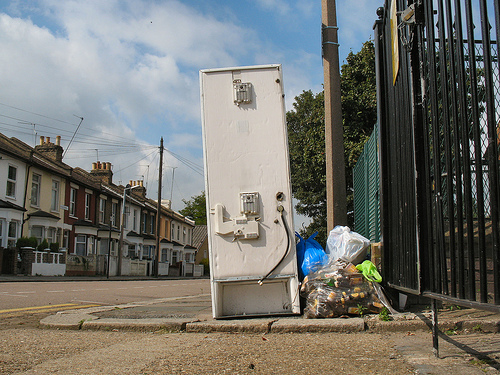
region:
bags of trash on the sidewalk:
[292, 216, 402, 333]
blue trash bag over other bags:
[296, 222, 334, 285]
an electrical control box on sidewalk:
[183, 52, 315, 331]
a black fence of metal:
[366, 0, 498, 345]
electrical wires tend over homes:
[1, 98, 203, 173]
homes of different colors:
[5, 128, 202, 285]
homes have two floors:
[1, 132, 206, 296]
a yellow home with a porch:
[16, 132, 71, 273]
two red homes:
[61, 159, 126, 275]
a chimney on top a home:
[26, 125, 69, 161]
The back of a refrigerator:
[195, 65, 307, 320]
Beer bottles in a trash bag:
[310, 268, 379, 318]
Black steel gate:
[420, 0, 499, 298]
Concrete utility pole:
[317, 2, 352, 314]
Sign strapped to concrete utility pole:
[313, 13, 346, 67]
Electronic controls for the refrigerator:
[215, 188, 270, 245]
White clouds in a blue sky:
[58, 13, 196, 107]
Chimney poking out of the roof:
[85, 155, 115, 187]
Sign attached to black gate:
[387, 1, 401, 82]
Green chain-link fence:
[347, 122, 377, 232]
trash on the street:
[292, 210, 440, 362]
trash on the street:
[282, 250, 403, 327]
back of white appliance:
[201, 54, 298, 320]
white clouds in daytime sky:
[67, 26, 176, 91]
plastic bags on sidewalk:
[294, 217, 376, 316]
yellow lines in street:
[10, 298, 87, 326]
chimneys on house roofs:
[36, 131, 151, 205]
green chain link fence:
[347, 128, 379, 232]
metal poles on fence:
[390, 45, 489, 266]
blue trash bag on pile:
[291, 227, 331, 279]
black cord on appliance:
[255, 207, 292, 294]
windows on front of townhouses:
[44, 179, 151, 232]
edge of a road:
[159, 313, 184, 338]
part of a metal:
[432, 308, 442, 332]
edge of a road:
[148, 309, 194, 340]